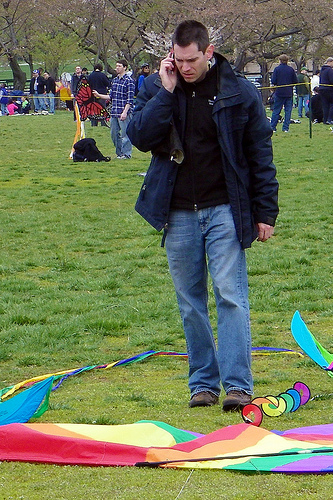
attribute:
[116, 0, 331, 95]
tree — in the picture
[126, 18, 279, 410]
person — in the picture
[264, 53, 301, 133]
person — in the picture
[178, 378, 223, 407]
foot — in the picture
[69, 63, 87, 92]
person — in the picture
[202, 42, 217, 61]
ear — in the picture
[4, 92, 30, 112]
kids — in the picture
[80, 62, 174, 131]
person — in the picture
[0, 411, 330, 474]
kite — in the picture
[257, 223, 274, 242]
hand — in the picture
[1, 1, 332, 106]
trees — in the picture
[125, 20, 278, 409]
man — in the picture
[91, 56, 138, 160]
man — in the picture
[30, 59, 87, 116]
person — in the picture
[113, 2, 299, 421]
person — in the picture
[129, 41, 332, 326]
man — in the picture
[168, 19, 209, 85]
head — in the picture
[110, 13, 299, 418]
guy — in the picture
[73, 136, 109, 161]
bag — in the picture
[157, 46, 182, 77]
cellphone — in the picture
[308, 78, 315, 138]
post — in the picture